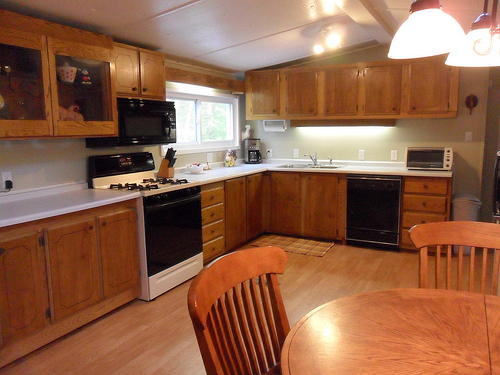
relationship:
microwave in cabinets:
[86, 97, 177, 146] [0, 9, 166, 138]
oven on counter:
[406, 146, 453, 170] [2, 150, 453, 230]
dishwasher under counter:
[347, 174, 400, 250] [2, 150, 453, 230]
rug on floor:
[251, 232, 334, 257] [3, 231, 500, 374]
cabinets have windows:
[0, 9, 166, 138] [1, 42, 114, 121]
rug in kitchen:
[251, 232, 334, 257] [5, 7, 499, 374]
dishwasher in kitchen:
[347, 174, 400, 250] [5, 7, 499, 374]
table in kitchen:
[281, 287, 499, 374] [5, 7, 499, 374]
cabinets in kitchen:
[245, 58, 459, 121] [5, 7, 499, 374]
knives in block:
[157, 147, 177, 176] [157, 160, 175, 179]